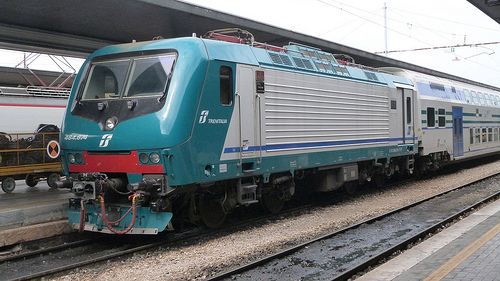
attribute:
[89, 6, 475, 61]
day — overcast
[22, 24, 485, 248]
view — outdoor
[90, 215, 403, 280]
tracks — empty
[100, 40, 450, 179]
train — blue, silver, red, white, teal, green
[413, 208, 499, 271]
line — yellow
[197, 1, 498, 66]
roof — flat, metal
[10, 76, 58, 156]
vehicle — second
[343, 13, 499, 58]
sky — overcast, white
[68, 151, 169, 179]
bumper — red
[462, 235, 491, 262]
stripe — yellow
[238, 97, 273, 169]
railing — silver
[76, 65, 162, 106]
windows — transparent, black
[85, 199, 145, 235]
wires — red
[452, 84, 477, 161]
door — double, blue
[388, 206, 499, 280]
platform — empty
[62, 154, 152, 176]
panel — red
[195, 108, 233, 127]
lettering — white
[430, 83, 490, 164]
car — passenger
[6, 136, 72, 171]
cart — yellow